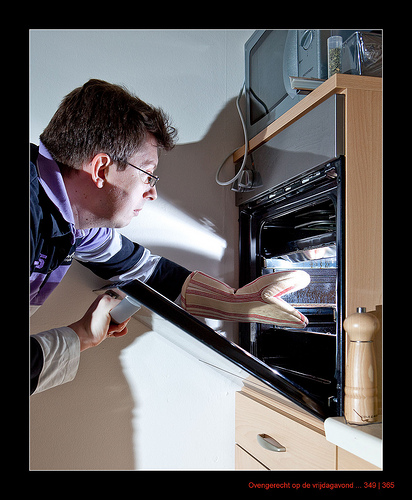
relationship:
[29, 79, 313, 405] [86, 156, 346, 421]
man reaching into oven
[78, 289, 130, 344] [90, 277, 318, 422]
hand holding oven door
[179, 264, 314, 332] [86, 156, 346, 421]
oven mitt reaching inside oven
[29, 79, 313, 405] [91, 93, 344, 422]
man reaching into on oven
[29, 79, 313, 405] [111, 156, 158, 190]
man wearing glasses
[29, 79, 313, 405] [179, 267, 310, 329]
man wearing oven mitt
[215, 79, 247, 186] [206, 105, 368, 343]
cord with microwave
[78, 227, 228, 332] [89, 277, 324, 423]
arm opening door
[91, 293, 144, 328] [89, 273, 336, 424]
handle on oven door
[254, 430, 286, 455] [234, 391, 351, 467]
handle on drawer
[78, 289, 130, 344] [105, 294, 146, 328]
hand grasps handle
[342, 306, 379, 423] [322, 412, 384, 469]
pepper shaker on counter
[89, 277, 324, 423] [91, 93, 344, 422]
door on oven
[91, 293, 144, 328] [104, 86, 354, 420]
handle on oven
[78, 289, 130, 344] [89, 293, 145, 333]
hand on handle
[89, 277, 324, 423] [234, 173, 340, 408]
door of oven